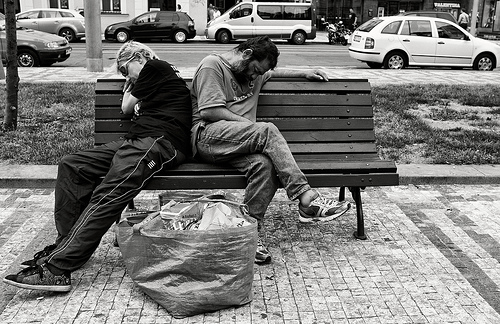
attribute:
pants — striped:
[41, 118, 211, 286]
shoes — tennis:
[237, 185, 352, 277]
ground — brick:
[4, 67, 499, 322]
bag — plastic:
[115, 190, 260, 320]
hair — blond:
[108, 33, 160, 70]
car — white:
[347, 16, 498, 71]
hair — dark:
[247, 31, 278, 64]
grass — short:
[19, 77, 140, 185]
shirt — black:
[112, 62, 204, 169]